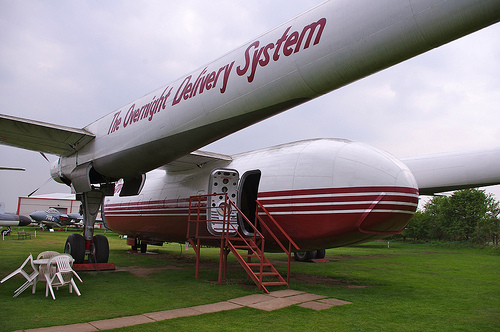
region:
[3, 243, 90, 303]
white table with plastic chairs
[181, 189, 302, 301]
stairway to enter the plane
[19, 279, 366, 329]
walkway leading to the stairs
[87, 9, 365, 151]
the words "The Overnight Delivery System"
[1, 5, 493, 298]
red and white airplane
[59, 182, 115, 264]
landing gear is down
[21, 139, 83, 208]
propeller on front of the wing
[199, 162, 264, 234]
door on the side of the airplane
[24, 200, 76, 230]
jet airplane in the background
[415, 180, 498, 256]
green leafy bush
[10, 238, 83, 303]
white chairs on the grass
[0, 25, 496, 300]
white plane on grass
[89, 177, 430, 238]
the stripe on the plane is red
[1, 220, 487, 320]
the grass is growing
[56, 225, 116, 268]
the tires are black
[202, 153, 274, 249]
the door is open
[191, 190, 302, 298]
the steps are red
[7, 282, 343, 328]
the path is red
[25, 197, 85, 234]
the plane is blue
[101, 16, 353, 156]
the letters are red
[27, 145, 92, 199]
A still plane propellor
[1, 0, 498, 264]
A red and white landed plane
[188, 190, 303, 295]
A red metal staircase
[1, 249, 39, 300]
A tipped white lawn chair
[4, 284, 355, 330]
A red stone walkway leading to stairs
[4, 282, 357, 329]
A sidewalk leading through the grass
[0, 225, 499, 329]
Grass yard around the plane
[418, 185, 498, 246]
Green trees at the edge of the grass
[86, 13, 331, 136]
Red words on the plane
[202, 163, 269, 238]
Door leading inside the plane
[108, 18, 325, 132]
words " The original delivery system"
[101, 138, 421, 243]
red and white striped plane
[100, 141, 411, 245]
cargo hold on plane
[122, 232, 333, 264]
wheels that come out for landing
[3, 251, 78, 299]
small table with chairs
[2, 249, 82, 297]
plastic white lawn furniture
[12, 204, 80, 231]
jet plane in back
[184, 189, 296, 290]
small ladder for boarding plane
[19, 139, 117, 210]
propeller on wing of plane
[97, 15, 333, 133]
free advertisement while flying plane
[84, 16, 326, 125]
red writing on the wind of the plane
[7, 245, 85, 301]
white table and chairs under the plane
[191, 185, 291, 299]
red steps going up into the plane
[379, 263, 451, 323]
green grass under the plane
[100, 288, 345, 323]
stepping stone walk way to the plane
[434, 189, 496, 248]
tree behind the plane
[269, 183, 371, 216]
red stripes on the plane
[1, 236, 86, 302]
plastic table and chairs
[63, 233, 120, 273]
landing gear down and blocked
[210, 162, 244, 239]
door of the plane